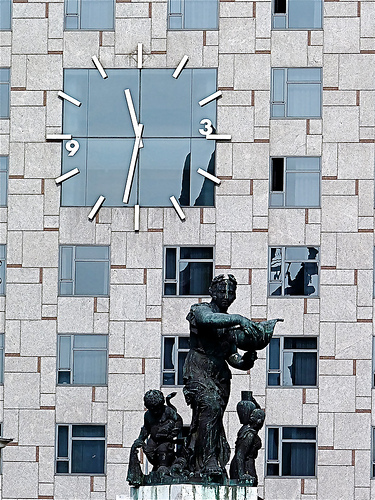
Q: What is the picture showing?
A: It is showing a hotel.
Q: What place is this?
A: It is a hotel.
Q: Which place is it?
A: It is a hotel.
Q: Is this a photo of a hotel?
A: Yes, it is showing a hotel.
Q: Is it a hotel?
A: Yes, it is a hotel.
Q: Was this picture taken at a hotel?
A: Yes, it was taken in a hotel.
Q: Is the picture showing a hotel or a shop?
A: It is showing a hotel.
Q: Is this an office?
A: No, it is a hotel.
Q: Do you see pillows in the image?
A: No, there are no pillows.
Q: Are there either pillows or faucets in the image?
A: No, there are no pillows or faucets.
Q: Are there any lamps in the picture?
A: No, there are no lamps.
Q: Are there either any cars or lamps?
A: No, there are no lamps or cars.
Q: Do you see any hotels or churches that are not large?
A: No, there is a hotel but it is large.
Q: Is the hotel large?
A: Yes, the hotel is large.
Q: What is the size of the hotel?
A: The hotel is large.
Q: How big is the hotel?
A: The hotel is large.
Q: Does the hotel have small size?
A: No, the hotel is large.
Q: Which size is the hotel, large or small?
A: The hotel is large.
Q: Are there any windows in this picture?
A: Yes, there is a window.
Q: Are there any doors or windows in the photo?
A: Yes, there is a window.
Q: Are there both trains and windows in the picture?
A: No, there is a window but no trains.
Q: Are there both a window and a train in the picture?
A: No, there is a window but no trains.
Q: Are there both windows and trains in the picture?
A: No, there is a window but no trains.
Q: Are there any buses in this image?
A: No, there are no buses.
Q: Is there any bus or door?
A: No, there are no buses or doors.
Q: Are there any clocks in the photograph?
A: Yes, there is a clock.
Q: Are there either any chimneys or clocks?
A: Yes, there is a clock.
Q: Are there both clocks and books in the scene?
A: No, there is a clock but no books.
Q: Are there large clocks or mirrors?
A: Yes, there is a large clock.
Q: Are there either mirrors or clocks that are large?
A: Yes, the clock is large.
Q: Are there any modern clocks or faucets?
A: Yes, there is a modern clock.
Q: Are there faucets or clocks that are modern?
A: Yes, the clock is modern.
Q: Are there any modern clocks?
A: Yes, there is a modern clock.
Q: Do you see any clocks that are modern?
A: Yes, there is a clock that is modern.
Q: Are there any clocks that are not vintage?
A: Yes, there is a modern clock.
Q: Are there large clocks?
A: Yes, there is a large clock.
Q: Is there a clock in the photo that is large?
A: Yes, there is a clock that is large.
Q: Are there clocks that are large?
A: Yes, there is a clock that is large.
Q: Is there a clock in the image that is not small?
A: Yes, there is a large clock.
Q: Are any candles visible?
A: No, there are no candles.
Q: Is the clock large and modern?
A: Yes, the clock is large and modern.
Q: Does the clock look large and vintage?
A: No, the clock is large but modern.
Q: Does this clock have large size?
A: Yes, the clock is large.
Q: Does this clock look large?
A: Yes, the clock is large.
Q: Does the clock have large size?
A: Yes, the clock is large.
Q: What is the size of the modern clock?
A: The clock is large.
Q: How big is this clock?
A: The clock is large.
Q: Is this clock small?
A: No, the clock is large.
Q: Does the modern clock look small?
A: No, the clock is large.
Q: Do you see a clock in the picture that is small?
A: No, there is a clock but it is large.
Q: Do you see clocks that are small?
A: No, there is a clock but it is large.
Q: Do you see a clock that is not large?
A: No, there is a clock but it is large.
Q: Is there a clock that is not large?
A: No, there is a clock but it is large.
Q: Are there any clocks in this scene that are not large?
A: No, there is a clock but it is large.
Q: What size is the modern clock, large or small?
A: The clock is large.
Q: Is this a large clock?
A: Yes, this is a large clock.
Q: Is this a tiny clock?
A: No, this is a large clock.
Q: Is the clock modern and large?
A: Yes, the clock is modern and large.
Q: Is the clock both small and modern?
A: No, the clock is modern but large.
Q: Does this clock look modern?
A: Yes, the clock is modern.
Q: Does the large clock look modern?
A: Yes, the clock is modern.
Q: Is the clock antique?
A: No, the clock is modern.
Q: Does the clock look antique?
A: No, the clock is modern.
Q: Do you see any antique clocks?
A: No, there is a clock but it is modern.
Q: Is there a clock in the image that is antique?
A: No, there is a clock but it is modern.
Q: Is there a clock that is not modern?
A: No, there is a clock but it is modern.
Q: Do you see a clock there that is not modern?
A: No, there is a clock but it is modern.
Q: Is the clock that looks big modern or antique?
A: The clock is modern.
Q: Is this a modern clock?
A: Yes, this is a modern clock.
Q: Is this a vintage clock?
A: No, this is a modern clock.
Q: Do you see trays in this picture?
A: No, there are no trays.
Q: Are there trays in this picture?
A: No, there are no trays.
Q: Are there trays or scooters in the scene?
A: No, there are no trays or scooters.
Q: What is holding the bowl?
A: The statue is holding the bowl.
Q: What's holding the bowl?
A: The statue is holding the bowl.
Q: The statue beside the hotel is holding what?
A: The statue is holding the bowl.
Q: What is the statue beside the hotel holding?
A: The statue is holding the bowl.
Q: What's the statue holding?
A: The statue is holding the bowl.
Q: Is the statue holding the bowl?
A: Yes, the statue is holding the bowl.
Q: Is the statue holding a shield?
A: No, the statue is holding the bowl.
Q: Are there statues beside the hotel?
A: Yes, there is a statue beside the hotel.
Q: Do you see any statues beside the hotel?
A: Yes, there is a statue beside the hotel.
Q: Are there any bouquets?
A: No, there are no bouquets.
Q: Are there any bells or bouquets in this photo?
A: No, there are no bouquets or bells.